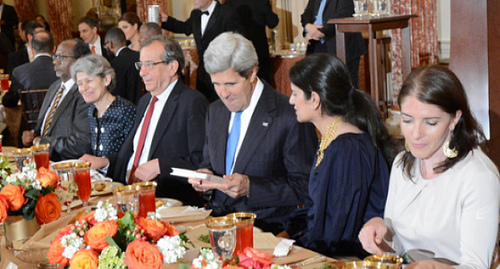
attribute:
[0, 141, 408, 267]
dinner — political 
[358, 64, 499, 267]
woman — smiling, looking, brunette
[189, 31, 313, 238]
man — john kerry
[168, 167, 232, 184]
book — held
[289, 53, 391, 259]
woman — looking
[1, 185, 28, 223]
roses — orange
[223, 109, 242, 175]
tie — blue, red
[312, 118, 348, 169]
necklace — gold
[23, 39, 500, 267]
people — rowed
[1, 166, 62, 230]
bouquet — floral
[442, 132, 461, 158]
earring — white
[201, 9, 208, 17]
tie — black, bow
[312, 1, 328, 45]
shirt — blue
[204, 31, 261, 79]
hair — dark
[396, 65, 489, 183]
hair — brown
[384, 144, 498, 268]
shirt — white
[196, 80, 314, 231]
jacket — black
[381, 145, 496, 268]
dress — white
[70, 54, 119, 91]
hair — grey